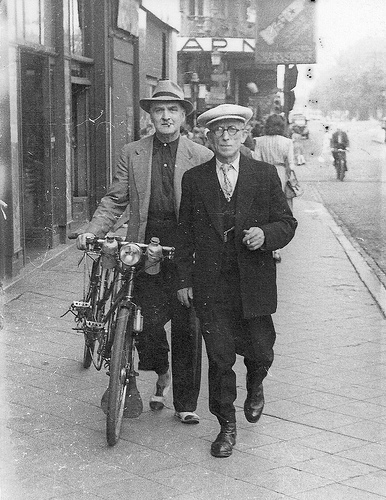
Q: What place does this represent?
A: It represents the pavement.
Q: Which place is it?
A: It is a pavement.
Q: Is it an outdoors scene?
A: Yes, it is outdoors.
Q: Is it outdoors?
A: Yes, it is outdoors.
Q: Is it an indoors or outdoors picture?
A: It is outdoors.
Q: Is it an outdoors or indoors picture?
A: It is outdoors.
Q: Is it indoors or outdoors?
A: It is outdoors.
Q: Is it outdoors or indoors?
A: It is outdoors.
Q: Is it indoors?
A: No, it is outdoors.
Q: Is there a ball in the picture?
A: No, there are no balls.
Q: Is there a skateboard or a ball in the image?
A: No, there are no balls or skateboards.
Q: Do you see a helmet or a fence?
A: No, there are no fences or helmets.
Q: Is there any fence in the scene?
A: No, there are no fences.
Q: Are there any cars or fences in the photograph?
A: No, there are no cars or fences.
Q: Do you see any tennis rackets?
A: No, there are no tennis rackets.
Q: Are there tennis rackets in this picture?
A: No, there are no tennis rackets.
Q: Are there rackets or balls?
A: No, there are no rackets or balls.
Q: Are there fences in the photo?
A: No, there are no fences.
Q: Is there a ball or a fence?
A: No, there are no fences or balls.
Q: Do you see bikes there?
A: Yes, there is a bike.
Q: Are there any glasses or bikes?
A: Yes, there is a bike.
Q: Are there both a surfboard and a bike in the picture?
A: No, there is a bike but no surfboards.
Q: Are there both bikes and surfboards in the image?
A: No, there is a bike but no surfboards.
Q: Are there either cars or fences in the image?
A: No, there are no fences or cars.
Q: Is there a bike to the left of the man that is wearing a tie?
A: Yes, there is a bike to the left of the man.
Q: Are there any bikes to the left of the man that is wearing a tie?
A: Yes, there is a bike to the left of the man.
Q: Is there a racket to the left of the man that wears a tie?
A: No, there is a bike to the left of the man.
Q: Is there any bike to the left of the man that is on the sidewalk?
A: Yes, there is a bike to the left of the man.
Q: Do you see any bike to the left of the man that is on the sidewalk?
A: Yes, there is a bike to the left of the man.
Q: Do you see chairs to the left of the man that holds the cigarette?
A: No, there is a bike to the left of the man.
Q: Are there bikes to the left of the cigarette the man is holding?
A: Yes, there is a bike to the left of the cigarette.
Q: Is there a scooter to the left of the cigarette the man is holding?
A: No, there is a bike to the left of the cigarette.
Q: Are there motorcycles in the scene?
A: Yes, there is a motorcycle.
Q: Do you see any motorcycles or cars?
A: Yes, there is a motorcycle.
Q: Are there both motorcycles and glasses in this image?
A: Yes, there are both a motorcycle and glasses.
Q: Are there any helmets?
A: No, there are no helmets.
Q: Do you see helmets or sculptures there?
A: No, there are no helmets or sculptures.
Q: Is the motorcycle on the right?
A: Yes, the motorcycle is on the right of the image.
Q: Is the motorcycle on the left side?
A: No, the motorcycle is on the right of the image.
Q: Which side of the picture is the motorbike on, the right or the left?
A: The motorbike is on the right of the image.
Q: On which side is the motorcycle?
A: The motorcycle is on the right of the image.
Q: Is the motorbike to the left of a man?
A: No, the motorbike is to the right of a man.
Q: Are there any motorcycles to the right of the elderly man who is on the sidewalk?
A: Yes, there is a motorcycle to the right of the man.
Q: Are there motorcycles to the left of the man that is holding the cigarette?
A: No, the motorcycle is to the right of the man.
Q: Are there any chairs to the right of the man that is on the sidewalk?
A: No, there is a motorcycle to the right of the man.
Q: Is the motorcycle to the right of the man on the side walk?
A: Yes, the motorcycle is to the right of the man.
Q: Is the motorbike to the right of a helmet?
A: No, the motorbike is to the right of the man.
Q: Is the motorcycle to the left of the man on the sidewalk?
A: No, the motorcycle is to the right of the man.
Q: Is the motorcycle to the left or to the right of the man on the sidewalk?
A: The motorcycle is to the right of the man.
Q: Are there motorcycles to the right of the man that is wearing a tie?
A: Yes, there is a motorcycle to the right of the man.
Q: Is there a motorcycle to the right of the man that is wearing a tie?
A: Yes, there is a motorcycle to the right of the man.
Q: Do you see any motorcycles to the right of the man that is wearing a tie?
A: Yes, there is a motorcycle to the right of the man.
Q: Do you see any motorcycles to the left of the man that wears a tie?
A: No, the motorcycle is to the right of the man.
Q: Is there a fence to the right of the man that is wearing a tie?
A: No, there is a motorcycle to the right of the man.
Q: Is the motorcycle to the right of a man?
A: Yes, the motorcycle is to the right of a man.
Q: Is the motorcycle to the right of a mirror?
A: No, the motorcycle is to the right of a man.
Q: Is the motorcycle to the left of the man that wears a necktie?
A: No, the motorcycle is to the right of the man.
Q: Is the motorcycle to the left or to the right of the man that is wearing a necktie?
A: The motorcycle is to the right of the man.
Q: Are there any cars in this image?
A: No, there are no cars.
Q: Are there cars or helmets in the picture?
A: No, there are no cars or helmets.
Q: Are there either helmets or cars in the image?
A: No, there are no cars or helmets.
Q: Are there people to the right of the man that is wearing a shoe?
A: Yes, there is a person to the right of the man.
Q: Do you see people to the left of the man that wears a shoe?
A: No, the person is to the right of the man.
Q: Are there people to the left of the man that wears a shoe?
A: No, the person is to the right of the man.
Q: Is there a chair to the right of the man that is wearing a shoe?
A: No, there is a person to the right of the man.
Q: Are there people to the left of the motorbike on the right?
A: Yes, there is a person to the left of the motorbike.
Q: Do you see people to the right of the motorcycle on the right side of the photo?
A: No, the person is to the left of the motorcycle.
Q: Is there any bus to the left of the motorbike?
A: No, there is a person to the left of the motorbike.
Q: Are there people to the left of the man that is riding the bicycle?
A: Yes, there is a person to the left of the man.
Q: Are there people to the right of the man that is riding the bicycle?
A: No, the person is to the left of the man.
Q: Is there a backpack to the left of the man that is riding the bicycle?
A: No, there is a person to the left of the man.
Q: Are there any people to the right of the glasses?
A: Yes, there is a person to the right of the glasses.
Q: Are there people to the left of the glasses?
A: No, the person is to the right of the glasses.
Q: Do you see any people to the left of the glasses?
A: No, the person is to the right of the glasses.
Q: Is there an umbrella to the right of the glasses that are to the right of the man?
A: No, there is a person to the right of the glasses.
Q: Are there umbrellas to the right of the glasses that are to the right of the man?
A: No, there is a person to the right of the glasses.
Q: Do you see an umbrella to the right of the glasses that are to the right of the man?
A: No, there is a person to the right of the glasses.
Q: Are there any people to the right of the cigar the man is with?
A: Yes, there is a person to the right of the cigar.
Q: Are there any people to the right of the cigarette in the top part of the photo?
A: Yes, there is a person to the right of the cigarette.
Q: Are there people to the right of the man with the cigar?
A: Yes, there is a person to the right of the man.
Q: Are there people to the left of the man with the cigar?
A: No, the person is to the right of the man.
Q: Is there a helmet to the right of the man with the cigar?
A: No, there is a person to the right of the man.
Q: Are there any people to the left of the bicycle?
A: Yes, there is a person to the left of the bicycle.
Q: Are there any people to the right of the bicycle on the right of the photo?
A: No, the person is to the left of the bicycle.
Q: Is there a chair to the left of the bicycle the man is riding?
A: No, there is a person to the left of the bicycle.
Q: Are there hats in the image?
A: Yes, there is a hat.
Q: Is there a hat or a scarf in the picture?
A: Yes, there is a hat.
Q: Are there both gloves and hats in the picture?
A: No, there is a hat but no gloves.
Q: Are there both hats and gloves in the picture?
A: No, there is a hat but no gloves.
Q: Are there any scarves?
A: No, there are no scarves.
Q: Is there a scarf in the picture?
A: No, there are no scarves.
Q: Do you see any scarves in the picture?
A: No, there are no scarves.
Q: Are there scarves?
A: No, there are no scarves.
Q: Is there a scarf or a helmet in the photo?
A: No, there are no scarves or helmets.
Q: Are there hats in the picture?
A: Yes, there is a hat.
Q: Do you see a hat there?
A: Yes, there is a hat.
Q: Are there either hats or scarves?
A: Yes, there is a hat.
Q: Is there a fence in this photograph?
A: No, there are no fences.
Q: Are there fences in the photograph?
A: No, there are no fences.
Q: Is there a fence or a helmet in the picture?
A: No, there are no fences or helmets.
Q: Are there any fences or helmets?
A: No, there are no fences or helmets.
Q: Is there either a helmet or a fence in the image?
A: No, there are no fences or helmets.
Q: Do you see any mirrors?
A: No, there are no mirrors.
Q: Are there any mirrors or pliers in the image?
A: No, there are no mirrors or pliers.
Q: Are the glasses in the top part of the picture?
A: Yes, the glasses are in the top of the image.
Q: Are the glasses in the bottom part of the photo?
A: No, the glasses are in the top of the image.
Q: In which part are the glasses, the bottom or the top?
A: The glasses are in the top of the image.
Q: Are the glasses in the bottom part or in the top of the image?
A: The glasses are in the top of the image.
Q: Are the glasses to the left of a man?
A: No, the glasses are to the right of a man.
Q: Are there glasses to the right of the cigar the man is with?
A: Yes, there are glasses to the right of the cigar.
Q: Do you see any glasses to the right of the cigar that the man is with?
A: Yes, there are glasses to the right of the cigar.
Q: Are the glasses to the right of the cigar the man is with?
A: Yes, the glasses are to the right of the cigar.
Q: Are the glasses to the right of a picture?
A: No, the glasses are to the right of the cigar.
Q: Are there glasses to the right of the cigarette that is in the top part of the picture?
A: Yes, there are glasses to the right of the cigarette.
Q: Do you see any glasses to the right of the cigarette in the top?
A: Yes, there are glasses to the right of the cigarette.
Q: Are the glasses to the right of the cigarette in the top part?
A: Yes, the glasses are to the right of the cigarette.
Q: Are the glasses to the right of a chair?
A: No, the glasses are to the right of the cigarette.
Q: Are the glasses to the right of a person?
A: No, the glasses are to the left of a person.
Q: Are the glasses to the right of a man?
A: Yes, the glasses are to the right of a man.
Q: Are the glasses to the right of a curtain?
A: No, the glasses are to the right of a man.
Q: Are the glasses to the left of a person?
A: Yes, the glasses are to the left of a person.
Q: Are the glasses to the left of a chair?
A: No, the glasses are to the left of a person.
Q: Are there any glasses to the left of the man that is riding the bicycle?
A: Yes, there are glasses to the left of the man.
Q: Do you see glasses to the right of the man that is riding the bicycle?
A: No, the glasses are to the left of the man.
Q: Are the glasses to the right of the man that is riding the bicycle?
A: No, the glasses are to the left of the man.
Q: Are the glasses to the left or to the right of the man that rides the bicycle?
A: The glasses are to the left of the man.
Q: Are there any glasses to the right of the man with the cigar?
A: Yes, there are glasses to the right of the man.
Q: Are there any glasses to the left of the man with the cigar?
A: No, the glasses are to the right of the man.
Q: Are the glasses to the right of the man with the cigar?
A: Yes, the glasses are to the right of the man.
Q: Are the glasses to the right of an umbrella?
A: No, the glasses are to the right of the man.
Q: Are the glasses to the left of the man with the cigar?
A: No, the glasses are to the right of the man.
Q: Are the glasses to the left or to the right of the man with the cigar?
A: The glasses are to the right of the man.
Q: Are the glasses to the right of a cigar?
A: Yes, the glasses are to the right of a cigar.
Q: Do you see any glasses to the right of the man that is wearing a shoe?
A: Yes, there are glasses to the right of the man.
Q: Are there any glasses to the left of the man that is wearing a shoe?
A: No, the glasses are to the right of the man.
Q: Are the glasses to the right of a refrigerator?
A: No, the glasses are to the right of a man.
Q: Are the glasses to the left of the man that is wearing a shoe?
A: No, the glasses are to the right of the man.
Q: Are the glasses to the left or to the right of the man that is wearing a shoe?
A: The glasses are to the right of the man.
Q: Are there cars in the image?
A: No, there are no cars.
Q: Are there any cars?
A: No, there are no cars.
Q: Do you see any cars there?
A: No, there are no cars.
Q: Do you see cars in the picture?
A: No, there are no cars.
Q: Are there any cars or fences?
A: No, there are no cars or fences.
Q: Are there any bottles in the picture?
A: Yes, there is a bottle.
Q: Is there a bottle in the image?
A: Yes, there is a bottle.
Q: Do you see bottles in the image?
A: Yes, there is a bottle.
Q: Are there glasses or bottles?
A: Yes, there is a bottle.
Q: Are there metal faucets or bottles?
A: Yes, there is a metal bottle.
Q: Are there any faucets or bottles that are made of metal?
A: Yes, the bottle is made of metal.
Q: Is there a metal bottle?
A: Yes, there is a metal bottle.